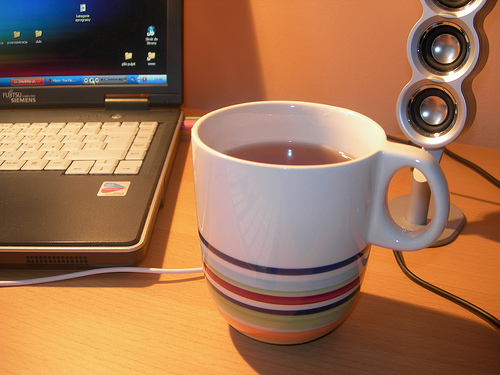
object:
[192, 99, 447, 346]
mug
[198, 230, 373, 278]
stripes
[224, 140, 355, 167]
tea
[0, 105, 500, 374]
table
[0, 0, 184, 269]
laptop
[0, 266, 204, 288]
cord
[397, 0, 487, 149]
speaker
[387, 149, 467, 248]
support post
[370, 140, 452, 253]
handle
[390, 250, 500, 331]
cord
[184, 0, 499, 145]
wall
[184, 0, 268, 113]
shadow of monitor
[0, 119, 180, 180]
keyboard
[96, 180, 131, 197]
logo sticker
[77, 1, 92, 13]
desktop icons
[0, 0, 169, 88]
laptop screen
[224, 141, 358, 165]
coffee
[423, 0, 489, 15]
top part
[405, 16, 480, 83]
center circle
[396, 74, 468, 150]
bottom circle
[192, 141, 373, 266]
upper half